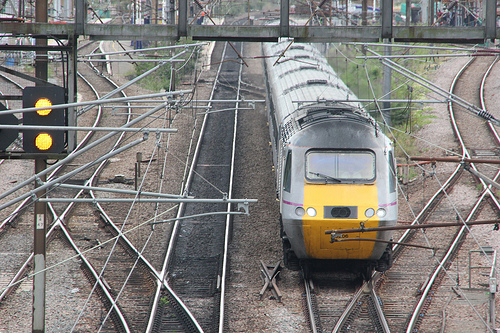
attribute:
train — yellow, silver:
[228, 36, 414, 256]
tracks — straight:
[167, 59, 242, 269]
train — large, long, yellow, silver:
[263, 59, 411, 290]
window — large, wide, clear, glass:
[305, 150, 376, 184]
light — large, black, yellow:
[21, 83, 66, 151]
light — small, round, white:
[305, 205, 315, 217]